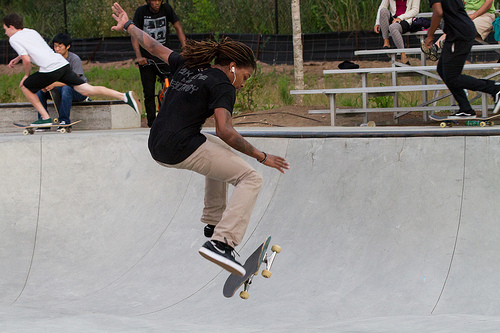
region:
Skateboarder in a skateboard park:
[96, 0, 287, 296]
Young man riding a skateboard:
[105, 0, 290, 275]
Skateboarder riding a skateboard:
[0, 10, 140, 135]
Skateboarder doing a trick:
[105, 0, 286, 295]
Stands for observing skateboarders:
[285, 0, 495, 126]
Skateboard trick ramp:
[0, 125, 496, 330]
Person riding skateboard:
[420, 0, 495, 125]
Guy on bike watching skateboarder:
[130, 0, 185, 125]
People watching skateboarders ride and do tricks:
[370, 0, 496, 66]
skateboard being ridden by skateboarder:
[221, 235, 279, 300]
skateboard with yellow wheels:
[220, 233, 282, 302]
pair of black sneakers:
[202, 223, 246, 278]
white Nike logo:
[208, 238, 228, 253]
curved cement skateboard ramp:
[317, 135, 497, 332]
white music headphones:
[227, 63, 237, 87]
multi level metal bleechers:
[288, 3, 496, 123]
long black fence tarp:
[0, 35, 496, 60]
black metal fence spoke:
[52, 0, 72, 40]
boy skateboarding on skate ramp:
[102, 1, 288, 301]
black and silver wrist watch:
[121, 17, 136, 32]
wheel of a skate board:
[266, 250, 281, 267]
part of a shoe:
[213, 245, 225, 250]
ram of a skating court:
[398, 211, 425, 241]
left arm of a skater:
[128, 34, 173, 56]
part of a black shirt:
[178, 103, 190, 128]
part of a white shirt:
[40, 42, 51, 54]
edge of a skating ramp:
[373, 126, 408, 137]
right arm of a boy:
[228, 143, 265, 151]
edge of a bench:
[319, 82, 368, 112]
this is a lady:
[137, 33, 299, 279]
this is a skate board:
[247, 246, 277, 272]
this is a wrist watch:
[124, 21, 131, 26]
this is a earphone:
[229, 69, 236, 81]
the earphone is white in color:
[228, 66, 235, 74]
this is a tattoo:
[236, 134, 252, 152]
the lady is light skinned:
[216, 111, 227, 121]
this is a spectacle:
[419, 45, 436, 60]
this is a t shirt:
[156, 101, 185, 139]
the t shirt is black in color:
[162, 112, 179, 129]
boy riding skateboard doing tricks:
[110, 3, 309, 299]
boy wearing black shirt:
[104, 5, 302, 301]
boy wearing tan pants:
[99, 3, 318, 300]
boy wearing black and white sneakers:
[107, 2, 332, 302]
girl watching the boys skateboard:
[374, 1, 416, 64]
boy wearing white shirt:
[3, 18, 143, 143]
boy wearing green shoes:
[0, 17, 152, 145]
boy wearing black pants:
[425, 1, 496, 127]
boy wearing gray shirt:
[41, 29, 93, 126]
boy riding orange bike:
[125, 1, 188, 135]